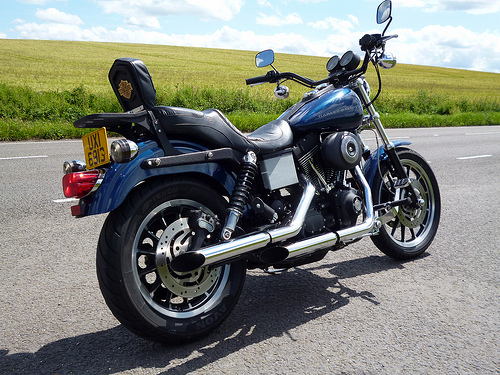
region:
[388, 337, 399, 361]
edge of a road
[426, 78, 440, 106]
part of the grass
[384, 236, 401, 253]
part of a wheel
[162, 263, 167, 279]
part of a wheel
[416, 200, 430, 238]
edge of a wheel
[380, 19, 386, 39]
part of a mirror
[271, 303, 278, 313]
part of a shadow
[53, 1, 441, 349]
a motorcycle parked on the highway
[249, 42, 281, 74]
the rear view mirror of a motorcycle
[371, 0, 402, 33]
the rear view mirror of a motorcycle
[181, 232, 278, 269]
the exhaust pipe of a motorcycle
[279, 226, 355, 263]
the exhaust pipe of a motorcycle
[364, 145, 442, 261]
a wheel of a motorcycle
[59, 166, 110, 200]
the tail light of a motorcycle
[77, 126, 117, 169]
a license plate of a motorcycle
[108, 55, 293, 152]
the seat of a motorcycle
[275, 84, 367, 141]
the gas tank of a motorcycle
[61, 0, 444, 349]
Blue Harley-Davidson Motorcycle.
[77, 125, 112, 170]
Yellow licence plate.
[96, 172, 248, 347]
Rear motorcycle wheel.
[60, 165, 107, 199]
Red tail light at rear of bike.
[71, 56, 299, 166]
Black leather motorcycle seat.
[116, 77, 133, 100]
Orange and black Harley-Davidson logo.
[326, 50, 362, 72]
Motorcycle speedometer and gauges.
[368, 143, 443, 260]
Front motorcycle wheel.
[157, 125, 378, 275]
Large engine with chrome exhaust pipes.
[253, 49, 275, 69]
Side rearview mirror.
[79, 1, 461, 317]
a motorcycle is parked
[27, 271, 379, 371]
shadow of the bike on the street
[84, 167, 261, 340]
the tire is black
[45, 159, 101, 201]
the brake light is red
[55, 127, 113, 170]
the license plate is yellow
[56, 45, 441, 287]
the bike is blue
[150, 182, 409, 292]
the pipes are silver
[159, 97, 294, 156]
the seat is black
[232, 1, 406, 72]
the mirrors are reflecting the clouds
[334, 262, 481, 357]
the street is grey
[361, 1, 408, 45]
right rear view motorcycle mirror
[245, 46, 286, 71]
left rear view motorcycle mirror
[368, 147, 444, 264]
front tire on a motorcycle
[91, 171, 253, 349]
rear tire on a motorcycle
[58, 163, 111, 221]
motorcycle brake light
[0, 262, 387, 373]
shadow cast by a motorcycle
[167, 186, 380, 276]
two motorcycle exhaust pipes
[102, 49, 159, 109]
Harley Davidson motorcycle seat back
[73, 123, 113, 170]
yellow motorcycle license plate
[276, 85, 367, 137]
blue motorcycle gas tank